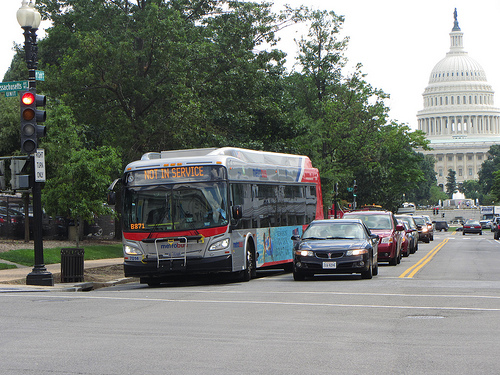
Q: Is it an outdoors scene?
A: Yes, it is outdoors.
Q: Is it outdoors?
A: Yes, it is outdoors.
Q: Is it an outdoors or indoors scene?
A: It is outdoors.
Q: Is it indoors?
A: No, it is outdoors.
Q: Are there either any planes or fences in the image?
A: No, there are no fences or planes.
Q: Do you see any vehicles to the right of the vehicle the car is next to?
A: Yes, there is a vehicle to the right of the bus.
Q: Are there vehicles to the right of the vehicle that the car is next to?
A: Yes, there is a vehicle to the right of the bus.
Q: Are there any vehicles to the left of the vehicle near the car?
A: No, the vehicle is to the right of the bus.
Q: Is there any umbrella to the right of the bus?
A: No, there is a vehicle to the right of the bus.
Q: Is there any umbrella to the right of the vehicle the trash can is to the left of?
A: No, there is a vehicle to the right of the bus.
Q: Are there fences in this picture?
A: No, there are no fences.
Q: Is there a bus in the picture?
A: Yes, there is a bus.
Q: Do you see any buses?
A: Yes, there is a bus.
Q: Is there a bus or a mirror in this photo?
A: Yes, there is a bus.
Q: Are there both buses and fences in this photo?
A: No, there is a bus but no fences.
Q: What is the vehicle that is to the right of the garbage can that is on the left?
A: The vehicle is a bus.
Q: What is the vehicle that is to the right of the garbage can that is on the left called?
A: The vehicle is a bus.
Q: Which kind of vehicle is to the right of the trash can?
A: The vehicle is a bus.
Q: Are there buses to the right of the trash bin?
A: Yes, there is a bus to the right of the trash bin.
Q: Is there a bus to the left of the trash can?
A: No, the bus is to the right of the trash can.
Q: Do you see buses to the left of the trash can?
A: No, the bus is to the right of the trash can.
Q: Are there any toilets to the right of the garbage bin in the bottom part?
A: No, there is a bus to the right of the trashcan.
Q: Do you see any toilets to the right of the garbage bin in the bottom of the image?
A: No, there is a bus to the right of the trashcan.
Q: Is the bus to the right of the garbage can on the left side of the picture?
A: Yes, the bus is to the right of the garbage bin.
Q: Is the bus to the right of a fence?
A: No, the bus is to the right of the garbage bin.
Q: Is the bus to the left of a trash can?
A: No, the bus is to the right of a trash can.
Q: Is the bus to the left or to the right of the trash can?
A: The bus is to the right of the trash can.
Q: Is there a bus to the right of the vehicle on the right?
A: No, the bus is to the left of the vehicle.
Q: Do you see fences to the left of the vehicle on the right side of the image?
A: No, there is a bus to the left of the vehicle.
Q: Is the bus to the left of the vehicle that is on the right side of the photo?
A: Yes, the bus is to the left of the vehicle.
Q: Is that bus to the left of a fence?
A: No, the bus is to the left of the vehicle.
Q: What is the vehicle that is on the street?
A: The vehicle is a bus.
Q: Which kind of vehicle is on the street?
A: The vehicle is a bus.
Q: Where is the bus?
A: The bus is on the street.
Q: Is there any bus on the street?
A: Yes, there is a bus on the street.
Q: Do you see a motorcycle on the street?
A: No, there is a bus on the street.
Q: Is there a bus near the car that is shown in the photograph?
A: Yes, there is a bus near the car.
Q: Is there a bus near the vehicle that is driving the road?
A: Yes, there is a bus near the car.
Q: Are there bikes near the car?
A: No, there is a bus near the car.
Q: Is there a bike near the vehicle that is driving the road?
A: No, there is a bus near the car.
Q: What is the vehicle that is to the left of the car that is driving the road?
A: The vehicle is a bus.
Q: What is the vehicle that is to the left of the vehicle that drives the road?
A: The vehicle is a bus.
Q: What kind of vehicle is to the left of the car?
A: The vehicle is a bus.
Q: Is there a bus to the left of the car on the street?
A: Yes, there is a bus to the left of the car.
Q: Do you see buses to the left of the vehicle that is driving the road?
A: Yes, there is a bus to the left of the car.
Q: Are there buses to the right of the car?
A: No, the bus is to the left of the car.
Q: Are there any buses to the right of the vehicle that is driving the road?
A: No, the bus is to the left of the car.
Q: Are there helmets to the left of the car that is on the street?
A: No, there is a bus to the left of the car.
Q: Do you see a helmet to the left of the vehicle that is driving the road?
A: No, there is a bus to the left of the car.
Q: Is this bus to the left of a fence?
A: No, the bus is to the left of the car.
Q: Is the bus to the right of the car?
A: No, the bus is to the left of the car.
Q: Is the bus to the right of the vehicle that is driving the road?
A: No, the bus is to the left of the car.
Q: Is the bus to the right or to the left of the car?
A: The bus is to the left of the car.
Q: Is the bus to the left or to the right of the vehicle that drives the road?
A: The bus is to the left of the car.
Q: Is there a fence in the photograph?
A: No, there are no fences.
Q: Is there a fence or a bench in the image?
A: No, there are no fences or benches.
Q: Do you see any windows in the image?
A: Yes, there are windows.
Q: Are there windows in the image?
A: Yes, there are windows.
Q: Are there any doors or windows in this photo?
A: Yes, there are windows.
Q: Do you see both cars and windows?
A: Yes, there are both windows and a car.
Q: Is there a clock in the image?
A: No, there are no clocks.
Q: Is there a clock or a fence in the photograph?
A: No, there are no clocks or fences.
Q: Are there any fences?
A: No, there are no fences.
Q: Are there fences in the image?
A: No, there are no fences.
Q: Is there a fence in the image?
A: No, there are no fences.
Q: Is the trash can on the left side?
A: Yes, the trash can is on the left of the image.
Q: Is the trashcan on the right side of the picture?
A: No, the trashcan is on the left of the image.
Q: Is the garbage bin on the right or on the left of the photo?
A: The garbage bin is on the left of the image.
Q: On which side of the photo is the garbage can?
A: The garbage can is on the left of the image.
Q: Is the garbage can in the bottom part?
A: Yes, the garbage can is in the bottom of the image.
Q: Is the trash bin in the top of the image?
A: No, the trash bin is in the bottom of the image.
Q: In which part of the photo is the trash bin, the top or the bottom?
A: The trash bin is in the bottom of the image.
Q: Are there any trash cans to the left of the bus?
A: Yes, there is a trash can to the left of the bus.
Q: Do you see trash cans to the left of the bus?
A: Yes, there is a trash can to the left of the bus.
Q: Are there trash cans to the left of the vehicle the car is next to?
A: Yes, there is a trash can to the left of the bus.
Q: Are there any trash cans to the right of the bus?
A: No, the trash can is to the left of the bus.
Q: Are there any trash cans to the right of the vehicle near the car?
A: No, the trash can is to the left of the bus.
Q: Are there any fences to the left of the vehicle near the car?
A: No, there is a trash can to the left of the bus.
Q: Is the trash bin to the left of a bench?
A: No, the trash bin is to the left of the bus.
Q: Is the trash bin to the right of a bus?
A: No, the trash bin is to the left of a bus.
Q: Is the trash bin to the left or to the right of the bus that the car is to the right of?
A: The trash bin is to the left of the bus.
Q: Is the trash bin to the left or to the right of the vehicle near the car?
A: The trash bin is to the left of the bus.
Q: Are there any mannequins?
A: No, there are no mannequins.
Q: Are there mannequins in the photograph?
A: No, there are no mannequins.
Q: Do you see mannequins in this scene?
A: No, there are no mannequins.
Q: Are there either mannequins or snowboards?
A: No, there are no mannequins or snowboards.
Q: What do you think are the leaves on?
A: The leaves are on the tree.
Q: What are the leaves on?
A: The leaves are on the tree.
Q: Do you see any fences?
A: No, there are no fences.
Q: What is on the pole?
A: The sign is on the pole.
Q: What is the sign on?
A: The sign is on the pole.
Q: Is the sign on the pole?
A: Yes, the sign is on the pole.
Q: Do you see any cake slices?
A: No, there are no cake slices.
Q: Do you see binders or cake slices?
A: No, there are no cake slices or binders.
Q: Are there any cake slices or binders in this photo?
A: No, there are no cake slices or binders.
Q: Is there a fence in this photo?
A: No, there are no fences.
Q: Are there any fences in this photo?
A: No, there are no fences.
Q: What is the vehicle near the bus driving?
A: The car is driving the road.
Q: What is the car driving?
A: The car is driving the road.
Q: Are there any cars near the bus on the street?
A: Yes, there is a car near the bus.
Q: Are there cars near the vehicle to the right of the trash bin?
A: Yes, there is a car near the bus.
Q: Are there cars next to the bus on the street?
A: Yes, there is a car next to the bus.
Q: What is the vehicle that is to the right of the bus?
A: The vehicle is a car.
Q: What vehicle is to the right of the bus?
A: The vehicle is a car.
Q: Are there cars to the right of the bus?
A: Yes, there is a car to the right of the bus.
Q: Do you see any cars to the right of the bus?
A: Yes, there is a car to the right of the bus.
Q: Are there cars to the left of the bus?
A: No, the car is to the right of the bus.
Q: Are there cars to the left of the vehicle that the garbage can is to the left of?
A: No, the car is to the right of the bus.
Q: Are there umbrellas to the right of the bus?
A: No, there is a car to the right of the bus.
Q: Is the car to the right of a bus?
A: Yes, the car is to the right of a bus.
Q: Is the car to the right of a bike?
A: No, the car is to the right of a bus.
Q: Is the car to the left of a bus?
A: No, the car is to the right of a bus.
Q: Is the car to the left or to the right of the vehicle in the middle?
A: The car is to the right of the bus.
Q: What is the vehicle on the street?
A: The vehicle is a car.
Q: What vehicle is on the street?
A: The vehicle is a car.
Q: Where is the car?
A: The car is on the street.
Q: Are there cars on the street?
A: Yes, there is a car on the street.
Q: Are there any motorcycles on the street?
A: No, there is a car on the street.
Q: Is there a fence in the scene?
A: No, there are no fences.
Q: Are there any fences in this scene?
A: No, there are no fences.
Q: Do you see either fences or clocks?
A: No, there are no fences or clocks.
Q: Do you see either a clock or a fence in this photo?
A: No, there are no fences or clocks.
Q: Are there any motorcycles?
A: No, there are no motorcycles.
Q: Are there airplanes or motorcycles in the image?
A: No, there are no motorcycles or airplanes.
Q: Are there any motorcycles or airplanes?
A: No, there are no motorcycles or airplanes.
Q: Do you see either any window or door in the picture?
A: Yes, there is a window.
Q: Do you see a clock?
A: No, there are no clocks.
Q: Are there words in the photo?
A: Yes, there are words.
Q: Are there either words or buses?
A: Yes, there are words.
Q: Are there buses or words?
A: Yes, there are words.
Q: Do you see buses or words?
A: Yes, there are words.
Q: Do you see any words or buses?
A: Yes, there are words.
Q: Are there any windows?
A: Yes, there is a window.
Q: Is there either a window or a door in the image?
A: Yes, there is a window.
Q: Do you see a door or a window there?
A: Yes, there is a window.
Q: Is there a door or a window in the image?
A: Yes, there is a window.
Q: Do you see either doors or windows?
A: Yes, there is a window.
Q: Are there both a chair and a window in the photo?
A: No, there is a window but no chairs.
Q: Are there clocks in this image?
A: No, there are no clocks.